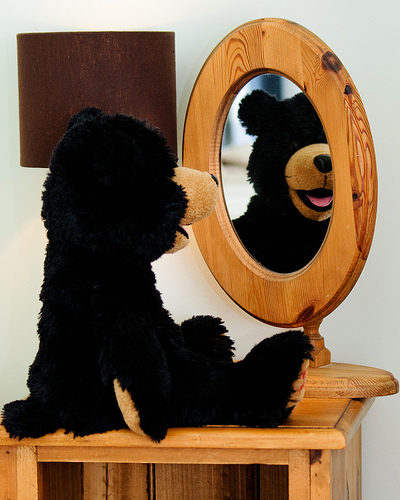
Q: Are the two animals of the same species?
A: Yes, all the animals are bears.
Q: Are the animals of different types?
A: No, all the animals are bears.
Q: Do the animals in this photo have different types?
A: No, all the animals are bears.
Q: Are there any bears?
A: Yes, there is a bear.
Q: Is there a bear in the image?
A: Yes, there is a bear.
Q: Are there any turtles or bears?
A: Yes, there is a bear.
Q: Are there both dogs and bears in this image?
A: No, there is a bear but no dogs.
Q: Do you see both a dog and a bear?
A: No, there is a bear but no dogs.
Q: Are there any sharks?
A: No, there are no sharks.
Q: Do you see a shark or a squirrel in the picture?
A: No, there are no sharks or squirrels.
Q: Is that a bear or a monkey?
A: That is a bear.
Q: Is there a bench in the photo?
A: No, there are no benches.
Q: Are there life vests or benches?
A: No, there are no benches or life vests.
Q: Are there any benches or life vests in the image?
A: No, there are no benches or life vests.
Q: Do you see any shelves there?
A: No, there are no shelves.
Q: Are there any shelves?
A: No, there are no shelves.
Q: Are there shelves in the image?
A: No, there are no shelves.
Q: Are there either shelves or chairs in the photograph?
A: No, there are no shelves or chairs.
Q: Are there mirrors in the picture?
A: Yes, there is a mirror.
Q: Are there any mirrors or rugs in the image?
A: Yes, there is a mirror.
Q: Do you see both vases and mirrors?
A: No, there is a mirror but no vases.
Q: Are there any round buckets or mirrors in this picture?
A: Yes, there is a round mirror.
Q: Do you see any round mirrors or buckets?
A: Yes, there is a round mirror.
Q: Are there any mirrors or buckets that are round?
A: Yes, the mirror is round.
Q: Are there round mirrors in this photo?
A: Yes, there is a round mirror.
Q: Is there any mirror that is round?
A: Yes, there is a mirror that is round.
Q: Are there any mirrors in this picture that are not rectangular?
A: Yes, there is a round mirror.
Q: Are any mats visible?
A: No, there are no mats.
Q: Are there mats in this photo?
A: No, there are no mats.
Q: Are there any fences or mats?
A: No, there are no mats or fences.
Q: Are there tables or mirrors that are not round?
A: No, there is a mirror but it is round.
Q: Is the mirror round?
A: Yes, the mirror is round.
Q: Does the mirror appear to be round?
A: Yes, the mirror is round.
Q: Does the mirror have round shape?
A: Yes, the mirror is round.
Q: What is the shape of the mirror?
A: The mirror is round.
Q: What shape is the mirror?
A: The mirror is round.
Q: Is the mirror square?
A: No, the mirror is round.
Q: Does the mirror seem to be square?
A: No, the mirror is round.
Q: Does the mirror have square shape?
A: No, the mirror is round.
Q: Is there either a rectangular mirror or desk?
A: No, there is a mirror but it is round.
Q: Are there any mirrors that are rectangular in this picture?
A: No, there is a mirror but it is round.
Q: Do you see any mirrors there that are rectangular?
A: No, there is a mirror but it is round.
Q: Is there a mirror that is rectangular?
A: No, there is a mirror but it is round.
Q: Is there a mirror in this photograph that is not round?
A: No, there is a mirror but it is round.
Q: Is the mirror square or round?
A: The mirror is round.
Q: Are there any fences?
A: No, there are no fences.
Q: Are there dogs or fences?
A: No, there are no fences or dogs.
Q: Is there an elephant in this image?
A: No, there are no elephants.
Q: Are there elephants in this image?
A: No, there are no elephants.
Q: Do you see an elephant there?
A: No, there are no elephants.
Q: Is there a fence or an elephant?
A: No, there are no elephants or fences.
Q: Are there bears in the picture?
A: Yes, there is a bear.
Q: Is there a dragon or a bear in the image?
A: Yes, there is a bear.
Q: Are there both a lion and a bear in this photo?
A: No, there is a bear but no lions.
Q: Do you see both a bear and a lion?
A: No, there is a bear but no lions.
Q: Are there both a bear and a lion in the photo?
A: No, there is a bear but no lions.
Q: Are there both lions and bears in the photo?
A: No, there is a bear but no lions.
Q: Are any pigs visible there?
A: No, there are no pigs.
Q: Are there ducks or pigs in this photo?
A: No, there are no pigs or ducks.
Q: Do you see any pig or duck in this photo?
A: No, there are no pigs or ducks.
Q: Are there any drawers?
A: No, there are no drawers.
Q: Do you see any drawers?
A: No, there are no drawers.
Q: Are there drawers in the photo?
A: No, there are no drawers.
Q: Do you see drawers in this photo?
A: No, there are no drawers.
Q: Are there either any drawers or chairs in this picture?
A: No, there are no drawers or chairs.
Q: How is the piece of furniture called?
A: The piece of furniture is a cupboard.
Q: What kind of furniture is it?
A: The piece of furniture is a cupboard.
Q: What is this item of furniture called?
A: This is a cupboard.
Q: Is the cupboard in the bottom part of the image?
A: Yes, the cupboard is in the bottom of the image.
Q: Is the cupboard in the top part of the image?
A: No, the cupboard is in the bottom of the image.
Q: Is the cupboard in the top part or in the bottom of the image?
A: The cupboard is in the bottom of the image.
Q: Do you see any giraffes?
A: No, there are no giraffes.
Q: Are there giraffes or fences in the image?
A: No, there are no giraffes or fences.